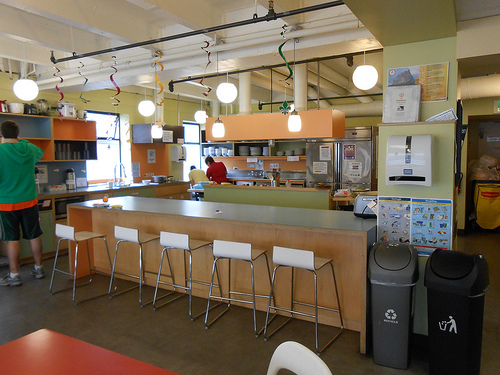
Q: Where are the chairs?
A: By the counter.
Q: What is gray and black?
A: Trash Bins.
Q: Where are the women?
A: In the kitchen.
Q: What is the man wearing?
A: Jacket and shorts.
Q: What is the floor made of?
A: Tile.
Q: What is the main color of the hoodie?
A: Green.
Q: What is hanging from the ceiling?
A: Lights.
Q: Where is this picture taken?
A: Restaurant.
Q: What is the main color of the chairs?
A: White.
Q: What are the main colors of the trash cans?
A: Black and grey.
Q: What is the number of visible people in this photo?
A: 3.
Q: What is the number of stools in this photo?
A: 5.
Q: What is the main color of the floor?
A: Brown.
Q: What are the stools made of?
A: Metal.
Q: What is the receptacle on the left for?
A: Recycling.